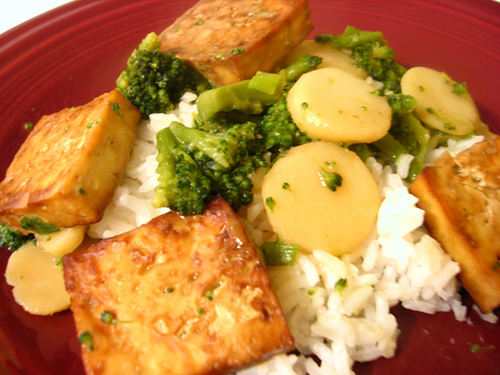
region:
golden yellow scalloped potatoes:
[260, 53, 415, 258]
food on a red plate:
[16, 2, 491, 357]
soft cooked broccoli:
[114, 39, 293, 194]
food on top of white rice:
[48, 22, 452, 357]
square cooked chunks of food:
[67, 213, 304, 361]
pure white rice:
[383, 200, 458, 320]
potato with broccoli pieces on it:
[252, 135, 402, 278]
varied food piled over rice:
[31, 9, 481, 352]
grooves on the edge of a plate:
[3, 7, 108, 84]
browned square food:
[37, 212, 322, 372]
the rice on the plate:
[292, 265, 395, 356]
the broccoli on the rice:
[170, 98, 252, 198]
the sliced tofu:
[15, 110, 118, 198]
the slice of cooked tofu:
[9, 110, 128, 217]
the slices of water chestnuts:
[275, 73, 373, 236]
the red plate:
[35, 26, 115, 81]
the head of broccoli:
[122, 53, 174, 105]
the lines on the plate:
[18, 22, 106, 69]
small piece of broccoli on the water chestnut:
[319, 164, 341, 194]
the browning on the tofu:
[171, 230, 277, 334]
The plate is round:
[21, 8, 101, 100]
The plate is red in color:
[67, 39, 495, 323]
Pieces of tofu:
[42, 39, 402, 359]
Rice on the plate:
[95, 89, 489, 364]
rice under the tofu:
[74, 73, 449, 364]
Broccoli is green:
[125, 49, 467, 197]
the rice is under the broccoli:
[125, 108, 432, 369]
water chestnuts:
[204, 46, 496, 260]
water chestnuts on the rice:
[205, 53, 472, 274]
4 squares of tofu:
[14, 35, 492, 372]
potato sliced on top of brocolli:
[263, 152, 379, 255]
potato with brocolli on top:
[261, 145, 383, 260]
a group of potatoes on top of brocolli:
[266, 60, 476, 243]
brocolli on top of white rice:
[131, 20, 428, 263]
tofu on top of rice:
[73, 216, 281, 373]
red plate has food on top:
[0, 20, 497, 373]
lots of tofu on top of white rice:
[0, 7, 498, 373]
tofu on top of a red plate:
[1, 0, 493, 340]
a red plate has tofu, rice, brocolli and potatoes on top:
[9, 46, 474, 373]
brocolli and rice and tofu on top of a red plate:
[73, 116, 256, 369]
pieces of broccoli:
[165, 122, 255, 199]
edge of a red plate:
[0, 0, 100, 80]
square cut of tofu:
[115, 200, 285, 365]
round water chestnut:
[260, 140, 380, 255]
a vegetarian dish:
[20, 0, 480, 365]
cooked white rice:
[305, 255, 450, 365]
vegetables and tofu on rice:
[30, 5, 415, 350]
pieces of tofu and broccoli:
[115, 0, 315, 66]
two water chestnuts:
[275, 60, 390, 250]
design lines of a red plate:
[21, 30, 101, 68]